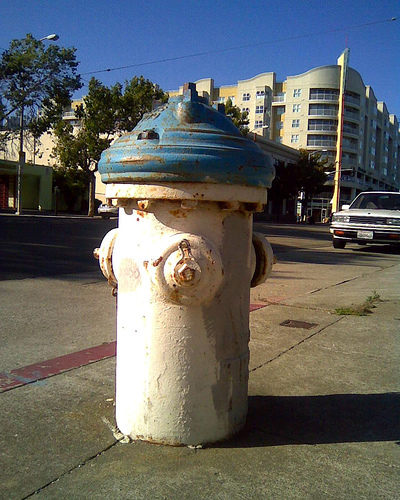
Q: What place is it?
A: It is a path.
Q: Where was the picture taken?
A: It was taken at the path.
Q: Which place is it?
A: It is a path.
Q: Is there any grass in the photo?
A: Yes, there is grass.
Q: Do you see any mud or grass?
A: Yes, there is grass.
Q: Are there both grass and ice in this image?
A: No, there is grass but no ice.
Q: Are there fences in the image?
A: No, there are no fences.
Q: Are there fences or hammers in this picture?
A: No, there are no fences or hammers.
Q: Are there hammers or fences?
A: No, there are no fences or hammers.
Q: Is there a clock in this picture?
A: No, there are no clocks.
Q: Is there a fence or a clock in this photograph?
A: No, there are no clocks or fences.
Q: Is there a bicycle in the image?
A: No, there are no bicycles.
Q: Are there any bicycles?
A: No, there are no bicycles.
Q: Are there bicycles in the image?
A: No, there are no bicycles.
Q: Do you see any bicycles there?
A: No, there are no bicycles.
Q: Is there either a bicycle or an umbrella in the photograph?
A: No, there are no bicycles or umbrellas.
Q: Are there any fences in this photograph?
A: No, there are no fences.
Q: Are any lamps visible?
A: Yes, there is a lamp.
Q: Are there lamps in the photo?
A: Yes, there is a lamp.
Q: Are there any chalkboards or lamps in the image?
A: Yes, there is a lamp.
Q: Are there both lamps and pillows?
A: No, there is a lamp but no pillows.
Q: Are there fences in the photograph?
A: No, there are no fences.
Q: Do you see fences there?
A: No, there are no fences.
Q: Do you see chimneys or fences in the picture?
A: No, there are no fences or chimneys.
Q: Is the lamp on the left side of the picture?
A: Yes, the lamp is on the left of the image.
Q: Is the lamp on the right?
A: No, the lamp is on the left of the image.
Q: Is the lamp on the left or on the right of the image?
A: The lamp is on the left of the image.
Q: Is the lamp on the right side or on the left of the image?
A: The lamp is on the left of the image.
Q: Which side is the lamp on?
A: The lamp is on the left of the image.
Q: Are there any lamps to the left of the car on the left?
A: Yes, there is a lamp to the left of the car.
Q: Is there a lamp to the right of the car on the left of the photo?
A: No, the lamp is to the left of the car.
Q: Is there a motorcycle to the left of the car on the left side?
A: No, there is a lamp to the left of the car.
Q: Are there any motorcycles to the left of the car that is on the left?
A: No, there is a lamp to the left of the car.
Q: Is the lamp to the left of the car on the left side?
A: Yes, the lamp is to the left of the car.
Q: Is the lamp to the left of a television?
A: No, the lamp is to the left of the car.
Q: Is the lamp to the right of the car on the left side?
A: No, the lamp is to the left of the car.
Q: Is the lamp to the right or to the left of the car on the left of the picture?
A: The lamp is to the left of the car.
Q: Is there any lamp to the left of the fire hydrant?
A: Yes, there is a lamp to the left of the fire hydrant.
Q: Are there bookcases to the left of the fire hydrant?
A: No, there is a lamp to the left of the fire hydrant.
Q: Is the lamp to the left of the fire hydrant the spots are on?
A: Yes, the lamp is to the left of the fire hydrant.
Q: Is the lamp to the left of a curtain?
A: No, the lamp is to the left of the fire hydrant.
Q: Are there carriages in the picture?
A: No, there are no carriages.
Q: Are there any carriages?
A: No, there are no carriages.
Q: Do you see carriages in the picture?
A: No, there are no carriages.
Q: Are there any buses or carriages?
A: No, there are no carriages or buses.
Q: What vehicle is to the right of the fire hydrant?
A: The vehicle is a car.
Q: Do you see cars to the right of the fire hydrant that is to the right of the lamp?
A: Yes, there is a car to the right of the hydrant.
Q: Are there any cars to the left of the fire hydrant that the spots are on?
A: No, the car is to the right of the fire hydrant.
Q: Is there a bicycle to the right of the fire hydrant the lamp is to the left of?
A: No, there is a car to the right of the fire hydrant.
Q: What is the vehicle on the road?
A: The vehicle is a car.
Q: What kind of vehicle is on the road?
A: The vehicle is a car.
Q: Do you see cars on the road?
A: Yes, there is a car on the road.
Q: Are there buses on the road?
A: No, there is a car on the road.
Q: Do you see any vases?
A: No, there are no vases.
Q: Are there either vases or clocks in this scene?
A: No, there are no vases or clocks.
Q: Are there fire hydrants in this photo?
A: Yes, there is a fire hydrant.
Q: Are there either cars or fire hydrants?
A: Yes, there is a fire hydrant.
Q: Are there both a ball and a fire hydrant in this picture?
A: No, there is a fire hydrant but no balls.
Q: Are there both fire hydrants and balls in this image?
A: No, there is a fire hydrant but no balls.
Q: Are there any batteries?
A: No, there are no batteries.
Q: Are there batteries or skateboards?
A: No, there are no batteries or skateboards.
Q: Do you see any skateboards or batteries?
A: No, there are no batteries or skateboards.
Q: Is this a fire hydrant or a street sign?
A: This is a fire hydrant.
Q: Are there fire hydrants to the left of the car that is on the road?
A: Yes, there is a fire hydrant to the left of the car.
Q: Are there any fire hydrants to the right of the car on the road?
A: No, the fire hydrant is to the left of the car.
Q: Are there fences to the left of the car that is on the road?
A: No, there is a fire hydrant to the left of the car.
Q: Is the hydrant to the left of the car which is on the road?
A: Yes, the hydrant is to the left of the car.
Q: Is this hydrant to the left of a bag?
A: No, the hydrant is to the left of the car.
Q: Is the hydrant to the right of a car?
A: No, the hydrant is to the left of a car.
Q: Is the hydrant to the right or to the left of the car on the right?
A: The hydrant is to the left of the car.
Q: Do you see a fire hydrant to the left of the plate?
A: Yes, there is a fire hydrant to the left of the plate.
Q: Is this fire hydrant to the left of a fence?
A: No, the fire hydrant is to the left of the plate.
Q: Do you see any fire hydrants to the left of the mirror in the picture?
A: Yes, there is a fire hydrant to the left of the mirror.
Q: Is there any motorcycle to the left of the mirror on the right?
A: No, there is a fire hydrant to the left of the mirror.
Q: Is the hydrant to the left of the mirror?
A: Yes, the hydrant is to the left of the mirror.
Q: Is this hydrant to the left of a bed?
A: No, the hydrant is to the left of the mirror.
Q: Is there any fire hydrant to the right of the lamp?
A: Yes, there is a fire hydrant to the right of the lamp.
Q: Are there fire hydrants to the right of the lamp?
A: Yes, there is a fire hydrant to the right of the lamp.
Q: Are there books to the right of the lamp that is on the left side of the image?
A: No, there is a fire hydrant to the right of the lamp.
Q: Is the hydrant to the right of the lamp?
A: Yes, the hydrant is to the right of the lamp.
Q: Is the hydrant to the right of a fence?
A: No, the hydrant is to the right of the lamp.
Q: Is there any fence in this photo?
A: No, there are no fences.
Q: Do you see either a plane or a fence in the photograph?
A: No, there are no fences or airplanes.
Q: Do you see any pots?
A: No, there are no pots.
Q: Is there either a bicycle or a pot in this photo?
A: No, there are no pots or bicycles.